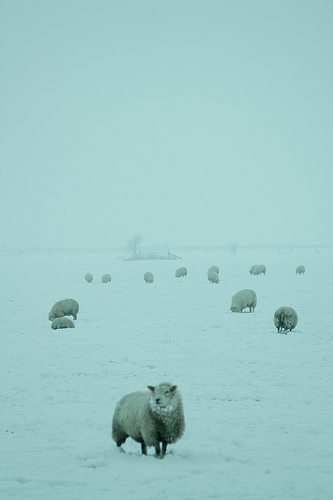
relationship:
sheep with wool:
[114, 362, 211, 454] [110, 391, 185, 443]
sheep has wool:
[77, 251, 320, 283] [128, 399, 143, 417]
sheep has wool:
[273, 306, 298, 333] [128, 399, 143, 417]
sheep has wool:
[49, 298, 80, 322] [128, 399, 143, 417]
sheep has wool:
[111, 380, 186, 460] [128, 399, 143, 417]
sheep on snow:
[111, 380, 186, 460] [129, 333, 311, 450]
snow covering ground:
[0, 248, 332, 499] [0, 248, 332, 498]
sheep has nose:
[111, 380, 186, 460] [154, 397, 163, 403]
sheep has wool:
[229, 288, 257, 313] [239, 293, 251, 302]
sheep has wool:
[273, 306, 298, 333] [284, 308, 297, 314]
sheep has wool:
[48, 297, 78, 318] [62, 300, 72, 306]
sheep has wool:
[50, 316, 75, 328] [58, 318, 66, 322]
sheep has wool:
[295, 265, 305, 275] [210, 270, 214, 276]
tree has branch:
[116, 232, 155, 260] [129, 242, 132, 246]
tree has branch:
[116, 232, 155, 260] [128, 249, 132, 254]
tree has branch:
[116, 232, 155, 260] [137, 235, 140, 242]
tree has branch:
[116, 232, 155, 260] [129, 241, 133, 248]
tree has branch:
[116, 232, 155, 260] [132, 243, 135, 252]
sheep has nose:
[197, 240, 289, 293] [152, 395, 162, 405]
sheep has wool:
[111, 380, 186, 460] [123, 403, 146, 421]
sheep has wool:
[49, 298, 80, 322] [64, 302, 74, 309]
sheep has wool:
[101, 271, 112, 284] [104, 275, 108, 279]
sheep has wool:
[142, 272, 153, 284] [146, 273, 150, 277]